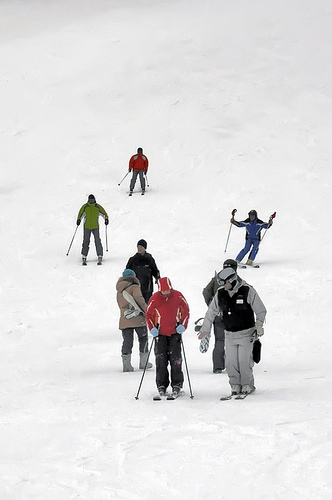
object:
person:
[67, 193, 109, 266]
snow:
[3, 1, 329, 500]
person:
[225, 209, 277, 269]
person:
[128, 148, 148, 197]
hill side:
[1, 3, 331, 270]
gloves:
[150, 325, 185, 337]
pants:
[226, 330, 254, 392]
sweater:
[143, 276, 190, 332]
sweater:
[129, 154, 149, 171]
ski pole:
[224, 209, 237, 253]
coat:
[116, 277, 148, 330]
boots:
[122, 351, 152, 372]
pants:
[154, 335, 184, 389]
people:
[115, 237, 267, 402]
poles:
[230, 210, 274, 265]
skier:
[145, 277, 190, 399]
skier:
[197, 268, 266, 401]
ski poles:
[135, 322, 195, 401]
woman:
[116, 269, 153, 373]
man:
[125, 239, 161, 298]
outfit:
[126, 252, 162, 296]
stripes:
[147, 277, 188, 326]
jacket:
[77, 201, 109, 230]